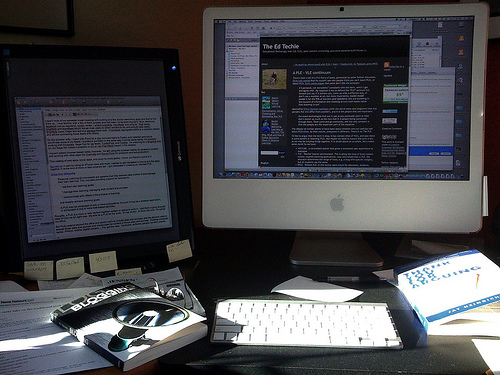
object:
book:
[393, 249, 499, 337]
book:
[48, 280, 209, 372]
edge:
[24, 235, 196, 279]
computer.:
[1, 38, 195, 278]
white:
[393, 253, 499, 338]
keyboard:
[208, 299, 409, 351]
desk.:
[0, 230, 500, 375]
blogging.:
[68, 280, 137, 314]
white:
[202, 3, 488, 233]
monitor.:
[197, 2, 489, 233]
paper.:
[270, 274, 366, 302]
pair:
[144, 261, 200, 311]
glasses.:
[142, 258, 200, 311]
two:
[0, 3, 489, 275]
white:
[210, 299, 408, 351]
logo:
[326, 195, 344, 212]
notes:
[87, 247, 121, 280]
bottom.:
[164, 236, 195, 265]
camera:
[336, 5, 345, 15]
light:
[169, 65, 178, 72]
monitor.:
[0, 43, 194, 272]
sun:
[0, 264, 500, 374]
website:
[256, 34, 412, 166]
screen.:
[213, 14, 470, 183]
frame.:
[195, 3, 488, 234]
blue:
[393, 247, 498, 338]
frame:
[1, 0, 78, 40]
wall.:
[0, 0, 500, 233]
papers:
[0, 287, 117, 374]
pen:
[309, 273, 380, 282]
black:
[49, 280, 205, 372]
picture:
[0, 1, 75, 36]